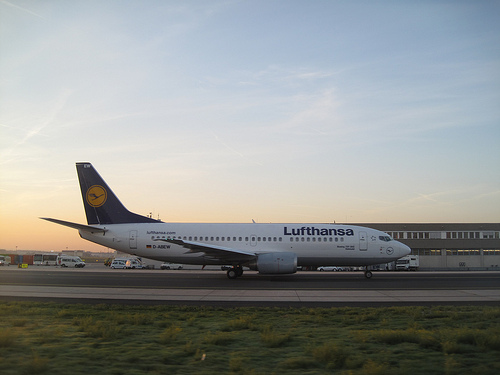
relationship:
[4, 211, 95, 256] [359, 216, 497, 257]
sunset behind airport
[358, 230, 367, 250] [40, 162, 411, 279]
door of airplane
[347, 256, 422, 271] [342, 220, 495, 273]
truck in front of building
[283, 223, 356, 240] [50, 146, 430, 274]
writing on a plane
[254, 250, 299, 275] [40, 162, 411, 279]
engine of airplane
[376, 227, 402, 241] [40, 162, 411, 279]
window of airplane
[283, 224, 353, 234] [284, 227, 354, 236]
logo of logo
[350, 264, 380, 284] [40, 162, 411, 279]
gear of airplane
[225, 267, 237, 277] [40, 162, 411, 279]
landing gear of airplane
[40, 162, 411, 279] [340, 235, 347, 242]
airplane has a window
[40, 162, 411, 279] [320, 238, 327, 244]
airplane with a window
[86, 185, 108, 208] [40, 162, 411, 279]
orange symbol on airplane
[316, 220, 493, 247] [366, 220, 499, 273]
roof on building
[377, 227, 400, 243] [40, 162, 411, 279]
window belonging to airplane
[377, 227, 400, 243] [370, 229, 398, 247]
window belonging to cockpit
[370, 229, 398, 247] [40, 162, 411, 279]
cockpit belonging to airplane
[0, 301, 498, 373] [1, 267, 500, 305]
grass in front of airport runway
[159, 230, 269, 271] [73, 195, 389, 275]
wing of plane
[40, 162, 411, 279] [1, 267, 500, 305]
airplane on airport runway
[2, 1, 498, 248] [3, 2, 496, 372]
sky behind airport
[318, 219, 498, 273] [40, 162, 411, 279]
building behind airplane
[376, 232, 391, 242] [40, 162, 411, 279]
window on airplane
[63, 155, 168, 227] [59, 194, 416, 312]
blue tail on plane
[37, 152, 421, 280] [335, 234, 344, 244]
airplane has window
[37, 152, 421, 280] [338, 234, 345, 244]
airplane has passenger window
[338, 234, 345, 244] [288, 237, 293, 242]
passenger window has passenger window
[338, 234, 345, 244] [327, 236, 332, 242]
passenger window has passenger window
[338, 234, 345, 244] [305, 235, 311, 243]
passenger window has passenger window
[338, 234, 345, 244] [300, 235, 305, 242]
passenger window has passenger window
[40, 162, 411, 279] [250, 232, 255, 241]
airplane has window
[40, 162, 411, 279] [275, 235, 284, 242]
airplane has window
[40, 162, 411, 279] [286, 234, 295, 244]
airplane has window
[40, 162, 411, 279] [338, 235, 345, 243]
airplane has window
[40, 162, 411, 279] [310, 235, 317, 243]
airplane has window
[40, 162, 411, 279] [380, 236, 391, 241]
airplane has windshield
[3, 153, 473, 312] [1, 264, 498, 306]
airport has airport runway